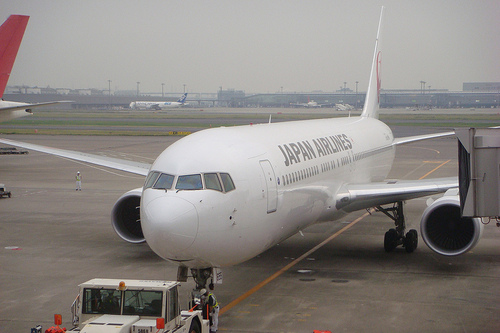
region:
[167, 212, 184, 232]
the plane is white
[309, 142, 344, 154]
the word is gray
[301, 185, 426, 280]
the plane is on the tarmack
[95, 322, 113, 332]
the car is white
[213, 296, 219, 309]
the vest is yellow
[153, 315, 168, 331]
the cover is orange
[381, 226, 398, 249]
the tire is black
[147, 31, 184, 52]
the sky is hazy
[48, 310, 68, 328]
the light is off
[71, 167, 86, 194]
the guy is standing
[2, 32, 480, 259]
white plane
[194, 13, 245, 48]
white clouds in blue sky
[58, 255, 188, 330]
white cart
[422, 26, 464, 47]
white clouds in blue sky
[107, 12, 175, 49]
white clouds in blue sky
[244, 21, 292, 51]
white clouds in blue sky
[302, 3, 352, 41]
white clouds in blue sky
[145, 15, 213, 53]
white clouds in blue sky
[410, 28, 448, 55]
white clouds in blue sky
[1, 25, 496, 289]
white and red airplane with black print writing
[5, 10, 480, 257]
white and red airplane with black writing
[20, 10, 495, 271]
white, black, and red airplane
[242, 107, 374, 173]
japan airlines printed on side of plane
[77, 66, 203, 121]
white and blue airplane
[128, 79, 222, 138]
blue and white airplane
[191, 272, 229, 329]
man servicing airplane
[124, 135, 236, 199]
windshield of airplane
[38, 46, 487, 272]
airplane with turbine engines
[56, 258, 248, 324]
cart for airport employee use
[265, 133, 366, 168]
Japan Airlines on the plane.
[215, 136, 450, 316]
Yellow line on the tarmac.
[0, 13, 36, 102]
The tail is red.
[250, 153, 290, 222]
The door is white.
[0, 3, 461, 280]
The plane is mostly white.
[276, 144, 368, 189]
Windows on the plane.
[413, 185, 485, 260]
Engine on the plane.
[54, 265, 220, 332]
Truck in front of the plane.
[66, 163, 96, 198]
Person on the tarmac.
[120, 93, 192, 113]
Plane in the distance.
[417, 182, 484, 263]
an engine of an airplane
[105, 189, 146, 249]
an engine of an airplane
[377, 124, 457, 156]
the tail wing of an airplane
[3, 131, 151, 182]
a wing of an airplane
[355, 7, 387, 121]
a tail of an airplane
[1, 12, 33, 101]
the tail of an airplane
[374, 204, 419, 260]
the landing gear of a plane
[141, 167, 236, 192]
the front window of a plane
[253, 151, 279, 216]
the door to a plane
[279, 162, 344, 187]
the windows on the side of an airplane